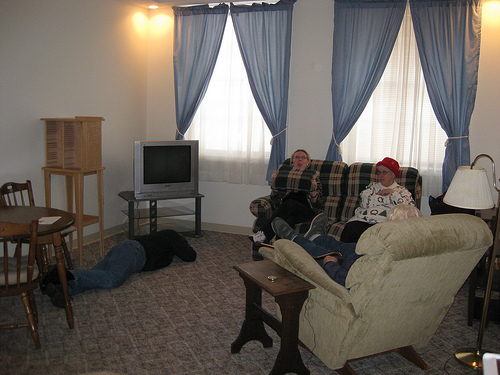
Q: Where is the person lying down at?
A: The floor.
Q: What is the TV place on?
A: A TV Stand.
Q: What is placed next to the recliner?
A: A brown side table.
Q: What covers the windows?
A: Blue curtains.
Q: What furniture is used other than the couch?
A: Tan recliner.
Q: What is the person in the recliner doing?
A: Recline.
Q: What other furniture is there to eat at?
A: A table and 2 chairs.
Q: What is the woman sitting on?
A: A plaid couch.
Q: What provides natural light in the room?
A: The windowS.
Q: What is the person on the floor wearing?
A: Blue jeans and a black shirt.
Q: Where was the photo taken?
A: In a living room.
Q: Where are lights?
A: On the wall.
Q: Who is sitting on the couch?
A: Two people.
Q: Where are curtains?
A: Over the windows.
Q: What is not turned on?
A: TV screen.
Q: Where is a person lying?
A: On the floor.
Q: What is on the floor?
A: A carpet.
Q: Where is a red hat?
A: On woman's head.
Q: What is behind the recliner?
A: A lamp.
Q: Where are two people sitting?
A: On a couch.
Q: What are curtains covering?
A: Windows.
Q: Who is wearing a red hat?
A: Woman on couch on the right.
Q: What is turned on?
A: Lights.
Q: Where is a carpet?
A: On the floor.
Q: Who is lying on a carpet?
A: A person.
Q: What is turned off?
A: TV screen.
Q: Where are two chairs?
A: Next to table.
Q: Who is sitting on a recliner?
A: A person.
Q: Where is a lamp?
A: Behind the chair.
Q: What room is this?
A: Living room.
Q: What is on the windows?
A: Curtains.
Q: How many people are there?
A: Four.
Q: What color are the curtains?
A: Blue and white.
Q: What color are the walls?
A: White.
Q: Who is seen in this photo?
A: Men and women.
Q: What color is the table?
A: Brown.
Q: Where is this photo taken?
A: In a living room.